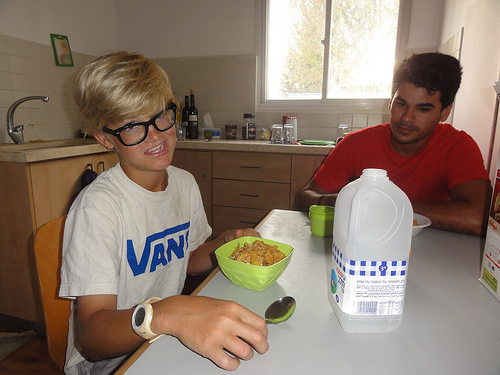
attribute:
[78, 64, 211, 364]
boy — eating, blonde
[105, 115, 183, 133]
glasses — black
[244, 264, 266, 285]
bowl — green, white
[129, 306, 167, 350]
watch — white, electronic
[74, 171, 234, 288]
shirt — white, red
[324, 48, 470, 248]
man — eating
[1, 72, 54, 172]
faucet — silver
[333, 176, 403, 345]
carton — empty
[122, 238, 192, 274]
letters — blue, vans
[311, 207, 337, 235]
cup — green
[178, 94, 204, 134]
bottles — wine